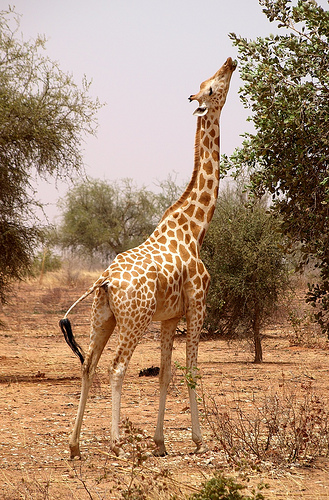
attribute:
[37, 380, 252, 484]
field — dirt 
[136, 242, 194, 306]
spots — brown, white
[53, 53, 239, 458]
giraffe — spotted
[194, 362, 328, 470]
branches — bare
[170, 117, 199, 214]
fringe — short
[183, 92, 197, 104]
horns — small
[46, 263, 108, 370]
skinny tail — skinny 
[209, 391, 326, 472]
bush — brown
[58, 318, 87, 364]
hair — black 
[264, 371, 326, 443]
leaves — brown